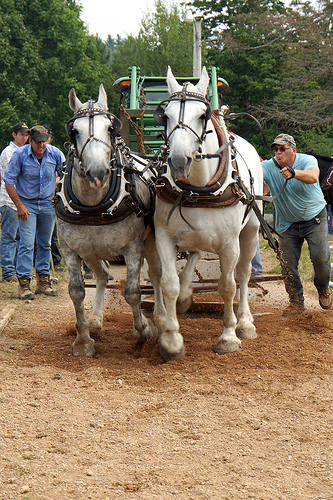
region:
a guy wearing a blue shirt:
[4, 119, 62, 286]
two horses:
[58, 65, 268, 362]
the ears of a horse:
[159, 62, 206, 99]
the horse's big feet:
[157, 322, 254, 361]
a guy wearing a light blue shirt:
[256, 129, 330, 309]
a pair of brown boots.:
[18, 274, 60, 308]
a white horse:
[150, 64, 264, 362]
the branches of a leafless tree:
[220, 8, 330, 139]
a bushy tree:
[0, 4, 87, 125]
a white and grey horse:
[47, 73, 151, 355]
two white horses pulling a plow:
[48, 62, 272, 369]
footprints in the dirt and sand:
[54, 376, 262, 454]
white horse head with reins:
[153, 60, 234, 190]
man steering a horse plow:
[260, 123, 331, 325]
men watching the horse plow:
[4, 117, 60, 309]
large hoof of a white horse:
[156, 317, 189, 366]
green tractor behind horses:
[113, 60, 231, 181]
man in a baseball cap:
[264, 130, 304, 168]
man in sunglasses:
[265, 130, 302, 167]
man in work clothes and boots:
[7, 118, 58, 304]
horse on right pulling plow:
[161, 76, 253, 341]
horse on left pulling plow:
[66, 92, 144, 351]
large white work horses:
[61, 84, 256, 330]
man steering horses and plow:
[258, 130, 328, 318]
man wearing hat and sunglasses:
[266, 135, 327, 318]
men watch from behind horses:
[12, 123, 53, 285]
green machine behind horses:
[106, 67, 223, 151]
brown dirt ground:
[3, 268, 328, 498]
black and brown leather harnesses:
[54, 97, 247, 222]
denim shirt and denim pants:
[13, 143, 57, 274]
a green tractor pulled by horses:
[104, 66, 241, 170]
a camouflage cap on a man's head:
[267, 130, 299, 147]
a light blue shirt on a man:
[260, 152, 329, 235]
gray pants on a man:
[276, 205, 331, 299]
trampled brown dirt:
[0, 261, 332, 498]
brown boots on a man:
[13, 271, 59, 300]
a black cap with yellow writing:
[11, 117, 28, 138]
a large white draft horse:
[146, 80, 263, 359]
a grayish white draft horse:
[51, 80, 159, 361]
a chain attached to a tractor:
[113, 89, 154, 158]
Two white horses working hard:
[44, 37, 290, 415]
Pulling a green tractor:
[88, 36, 276, 348]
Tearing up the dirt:
[24, 289, 328, 454]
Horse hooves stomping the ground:
[36, 253, 286, 386]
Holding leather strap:
[226, 106, 320, 269]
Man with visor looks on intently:
[5, 111, 76, 235]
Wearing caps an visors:
[8, 113, 60, 172]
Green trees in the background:
[26, 4, 307, 108]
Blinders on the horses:
[54, 99, 257, 147]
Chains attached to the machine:
[106, 63, 167, 174]